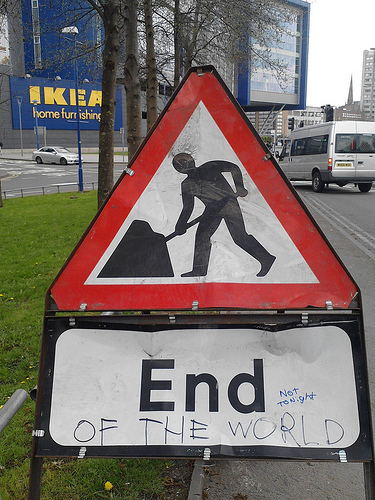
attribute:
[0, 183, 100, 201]
railing — metal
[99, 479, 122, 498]
flower — yellow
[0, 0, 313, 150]
building — blue and gray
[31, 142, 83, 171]
car — silver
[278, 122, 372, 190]
car — grey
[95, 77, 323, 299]
sign — red white and black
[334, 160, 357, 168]
license plate — yellow 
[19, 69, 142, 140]
sign — yellow and blue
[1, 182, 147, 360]
grass — green and short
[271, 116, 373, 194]
van — large silver, silver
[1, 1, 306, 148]
store — large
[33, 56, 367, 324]
sign — triangular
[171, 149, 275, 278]
figure — black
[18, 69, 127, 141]
sign — big blue and yellow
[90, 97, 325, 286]
center — white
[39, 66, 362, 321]
border — red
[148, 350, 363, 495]
cement — gray